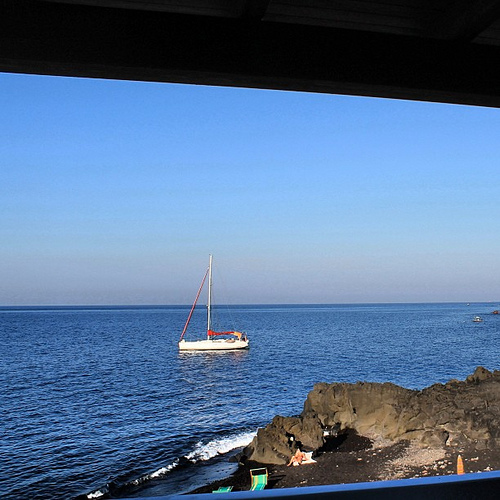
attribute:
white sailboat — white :
[160, 237, 256, 365]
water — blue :
[262, 300, 413, 380]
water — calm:
[33, 339, 168, 447]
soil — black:
[270, 460, 391, 484]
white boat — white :
[175, 253, 255, 352]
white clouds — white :
[30, 158, 85, 210]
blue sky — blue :
[1, 85, 498, 302]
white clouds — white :
[305, 234, 371, 278]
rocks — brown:
[355, 440, 467, 479]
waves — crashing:
[56, 371, 184, 410]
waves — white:
[194, 439, 228, 457]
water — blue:
[27, 325, 121, 375]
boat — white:
[174, 253, 261, 356]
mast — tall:
[181, 253, 221, 333]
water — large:
[35, 355, 147, 418]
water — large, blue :
[32, 364, 55, 393]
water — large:
[66, 384, 96, 398]